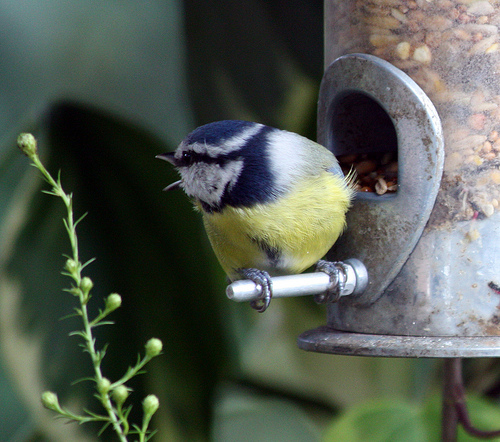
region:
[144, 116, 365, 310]
a little bird near a feeder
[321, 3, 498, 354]
feeder is full of grains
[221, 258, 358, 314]
feet of bird around a rod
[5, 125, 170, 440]
a plant with small buds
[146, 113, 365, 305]
birds facing to the left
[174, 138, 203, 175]
eye of birth is black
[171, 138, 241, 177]
a black line on head of bird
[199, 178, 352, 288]
part of the bird is yellow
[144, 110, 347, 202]
half of the body is gray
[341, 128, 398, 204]
grains on a feeder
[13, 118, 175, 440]
THIS IS A WEED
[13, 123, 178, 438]
THE WEED IS GREEN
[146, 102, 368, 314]
THIS IS A BIRD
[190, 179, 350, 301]
THE BIRD'S BELLY IS YELLOW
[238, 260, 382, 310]
THE BIRD'S FEET ARE BLACK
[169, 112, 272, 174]
THE BIRD HAS A WHITE STRIPE ON IT'S HEAD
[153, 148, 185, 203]
THE BIRD HAS AN OPEN BEAK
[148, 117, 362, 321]
THE BIRD IS PERCHED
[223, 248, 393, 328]
THE PERCH IS A SCREW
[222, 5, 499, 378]
THE FEEDER IS MADE OF METAL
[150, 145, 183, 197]
a bird's open beak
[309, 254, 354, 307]
a black bird foot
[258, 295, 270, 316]
a black nail on a bird's foot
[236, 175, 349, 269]
the yellow belly on a bird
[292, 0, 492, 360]
a full bird feeder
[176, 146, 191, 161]
a black eye on a bird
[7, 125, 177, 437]
a green plant covered in flower buds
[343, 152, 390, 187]
bird seed in a feeder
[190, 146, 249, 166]
a black stripe running back from a bird's eye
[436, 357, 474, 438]
the brown stem of a plant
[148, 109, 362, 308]
a small bird stand on a road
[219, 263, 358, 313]
a silver road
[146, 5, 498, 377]
a feeder in front a bird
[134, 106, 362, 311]
bird face to the left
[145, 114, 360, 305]
bird is color black, tan and yellow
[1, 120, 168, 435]
a plant in front a bird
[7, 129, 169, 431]
a plant with buttons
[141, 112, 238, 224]
a peak of bird is open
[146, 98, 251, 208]
head of bird is gray and black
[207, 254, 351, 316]
feet of bird is around a rod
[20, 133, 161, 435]
a tall green weed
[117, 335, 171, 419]
three bulbs of the weeds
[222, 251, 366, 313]
a small metal bird perch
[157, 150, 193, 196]
an opened bird beak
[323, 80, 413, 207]
open container of nuts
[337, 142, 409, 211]
small pile of nuts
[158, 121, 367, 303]
a yellow black and white bird on a perch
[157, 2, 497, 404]
a bird on a bird feeder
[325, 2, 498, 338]
a clear bird feeder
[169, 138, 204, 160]
black birds eye